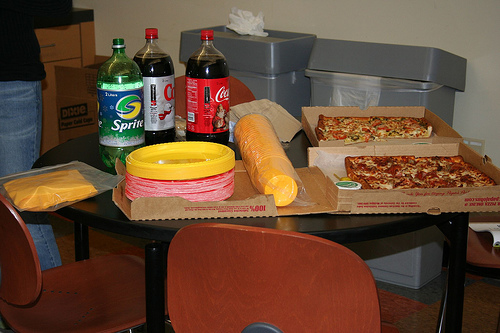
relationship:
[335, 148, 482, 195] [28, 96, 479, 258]
pizza kept on table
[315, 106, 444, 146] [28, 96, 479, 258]
pizza kept on table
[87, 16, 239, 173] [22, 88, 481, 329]
bottles kept on table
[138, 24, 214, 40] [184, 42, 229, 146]
lid of bottle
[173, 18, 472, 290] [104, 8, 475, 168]
plastic boxes near wall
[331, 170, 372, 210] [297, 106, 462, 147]
butter by box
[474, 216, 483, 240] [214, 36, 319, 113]
paper towel in garbage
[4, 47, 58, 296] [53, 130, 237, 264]
person standing by table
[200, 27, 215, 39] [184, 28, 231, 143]
cap to bottle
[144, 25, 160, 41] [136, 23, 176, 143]
lid on bottle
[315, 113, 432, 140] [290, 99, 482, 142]
pizza in box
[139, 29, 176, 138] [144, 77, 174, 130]
soda bottle has gray label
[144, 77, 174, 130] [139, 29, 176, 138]
gray label on soda bottle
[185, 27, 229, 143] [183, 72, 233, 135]
soda has red label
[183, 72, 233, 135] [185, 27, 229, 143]
red label on soda